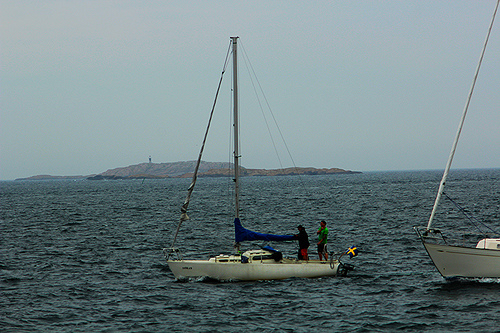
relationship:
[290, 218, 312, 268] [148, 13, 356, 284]
man on boat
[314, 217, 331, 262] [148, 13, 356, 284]
man on boat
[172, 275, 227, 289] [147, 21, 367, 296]
wave by boat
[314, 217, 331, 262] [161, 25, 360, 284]
man on boat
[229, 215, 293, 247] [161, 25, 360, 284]
flag on boat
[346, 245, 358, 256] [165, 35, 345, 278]
orange x on boat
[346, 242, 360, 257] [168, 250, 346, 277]
flag on back boat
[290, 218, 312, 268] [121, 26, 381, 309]
man on boat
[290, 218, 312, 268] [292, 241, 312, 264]
man has something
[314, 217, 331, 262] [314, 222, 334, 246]
man has green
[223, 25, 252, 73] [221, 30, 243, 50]
mast has top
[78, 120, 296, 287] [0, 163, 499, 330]
boat on water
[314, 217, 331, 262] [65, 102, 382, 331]
man on boat